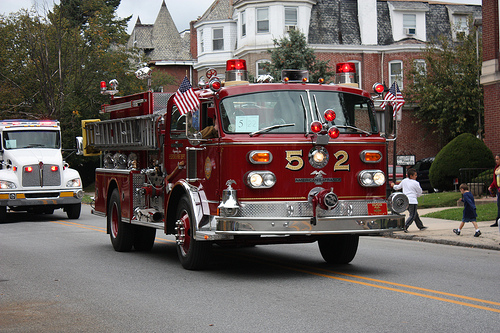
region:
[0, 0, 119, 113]
a big green tree.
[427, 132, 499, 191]
a beautiful dark green tree bush.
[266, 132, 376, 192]
a fire truck has the numbers 5 2.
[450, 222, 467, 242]
a boy is wearing grey sneakers.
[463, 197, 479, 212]
a boy is wearing a blue shirt.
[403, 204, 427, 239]
a boy is wearing grey and black pants.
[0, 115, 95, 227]
a white truck is in the street.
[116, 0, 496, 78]
a row of houses.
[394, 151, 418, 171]
a black and white sign.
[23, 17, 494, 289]
a fire truck is driving down the street.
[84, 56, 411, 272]
fire truck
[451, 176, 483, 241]
child walking on sidewalk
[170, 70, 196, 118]
American flag on fire engine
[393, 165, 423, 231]
child on the sidewalk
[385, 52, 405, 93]
window on a house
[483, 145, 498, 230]
Person walking on path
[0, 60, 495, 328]
street with two trucks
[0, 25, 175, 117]
tree in the background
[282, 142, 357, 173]
Engine number on fire truck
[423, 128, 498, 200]
shrub in front of building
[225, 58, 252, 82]
red firetruck light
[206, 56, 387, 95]
four red fire truck lights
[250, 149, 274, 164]
orange fire truck light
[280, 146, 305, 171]
the number 5 print on a fire truck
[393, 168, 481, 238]
two kids playing on a sidewalk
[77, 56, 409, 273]
firetruck on the street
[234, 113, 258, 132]
white paper behind the windshield reading 5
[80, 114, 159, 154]
ladder on the side of a fire truck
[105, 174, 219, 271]
two wheels on a fire truck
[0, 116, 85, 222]
white vehicle on the street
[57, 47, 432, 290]
the fire truck in the street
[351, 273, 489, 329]
the lines painted in the street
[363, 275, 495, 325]
the lines are yellow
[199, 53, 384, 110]
the lights above the fire truck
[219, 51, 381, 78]
the red lights are on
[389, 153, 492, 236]
children on the sidewalk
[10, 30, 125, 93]
the trees with green leaves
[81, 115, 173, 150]
the ladder on the fire truck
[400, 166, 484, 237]
children playing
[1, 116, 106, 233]
the truck behind the fire truck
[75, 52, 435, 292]
fire truck driving down the road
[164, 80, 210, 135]
American flag hanging from the truck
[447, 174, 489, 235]
little kid walking down the street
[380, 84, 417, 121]
American flag blowing in the wind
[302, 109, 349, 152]
three orange lights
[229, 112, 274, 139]
sign in the window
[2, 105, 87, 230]
white truck with orange lights on it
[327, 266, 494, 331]
two parallel yellow lines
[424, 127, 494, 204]
small dark green bush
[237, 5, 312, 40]
row of three windows